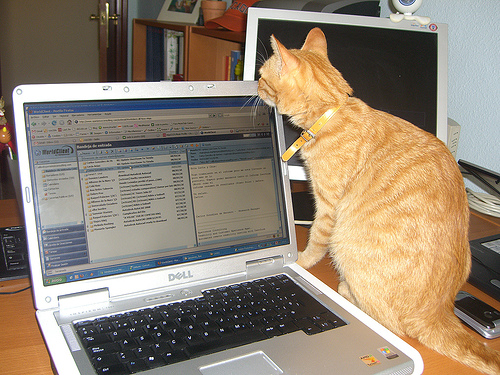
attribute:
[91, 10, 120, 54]
handle — gold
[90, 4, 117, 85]
door — wooden, open, white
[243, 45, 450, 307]
cat — tabby, red, sitting, brownish, brown, orange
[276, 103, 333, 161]
collar — yellow, orange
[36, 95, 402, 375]
laptop — open, on, dell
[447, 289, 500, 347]
phone — black, silvery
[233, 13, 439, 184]
monitor — off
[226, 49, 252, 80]
book — blue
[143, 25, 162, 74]
book — blue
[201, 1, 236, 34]
pot — brown, flower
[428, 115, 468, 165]
modem — white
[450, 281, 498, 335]
cellphone — black, grey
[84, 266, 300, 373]
keyboard — black, white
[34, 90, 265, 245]
screen — lit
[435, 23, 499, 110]
wall — white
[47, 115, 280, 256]
software — blue, white, gray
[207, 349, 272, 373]
pad — silver, gray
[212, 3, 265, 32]
cap — orange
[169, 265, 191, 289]
writing — silver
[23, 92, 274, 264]
monitor — gray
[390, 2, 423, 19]
camera — webcam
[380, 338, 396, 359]
logo — windows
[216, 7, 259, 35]
hat — red, visor